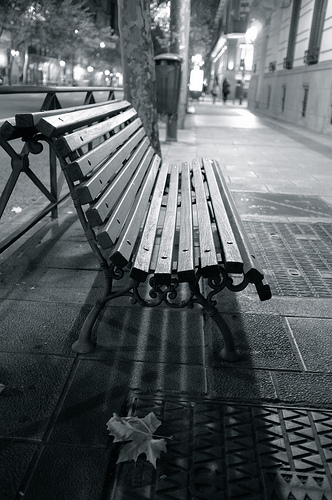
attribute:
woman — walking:
[222, 79, 230, 101]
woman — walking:
[209, 74, 220, 100]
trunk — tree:
[116, 1, 161, 165]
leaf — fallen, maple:
[107, 409, 174, 467]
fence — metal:
[1, 93, 127, 258]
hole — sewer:
[155, 379, 302, 478]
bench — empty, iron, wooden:
[11, 97, 271, 362]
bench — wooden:
[45, 88, 279, 359]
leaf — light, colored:
[106, 409, 167, 467]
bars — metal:
[282, 0, 296, 66]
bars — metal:
[307, 0, 322, 63]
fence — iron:
[0, 88, 116, 252]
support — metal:
[32, 134, 256, 376]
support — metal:
[133, 167, 226, 233]